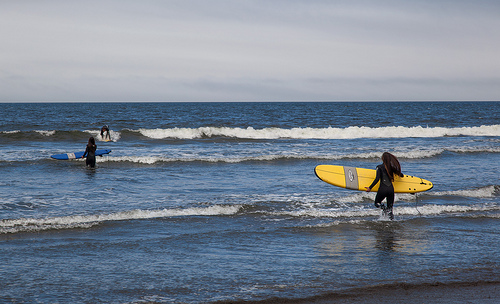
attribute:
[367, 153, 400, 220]
surfer — present, female, standing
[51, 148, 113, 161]
surfboard — blue, yellow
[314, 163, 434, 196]
surfboard — yellow, long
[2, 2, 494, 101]
sky — cloudy, grey, empty, gray, hazy, blue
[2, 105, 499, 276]
ocean — beautiful, blue, calm, here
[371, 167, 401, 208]
wetsuit — here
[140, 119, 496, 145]
waves — white